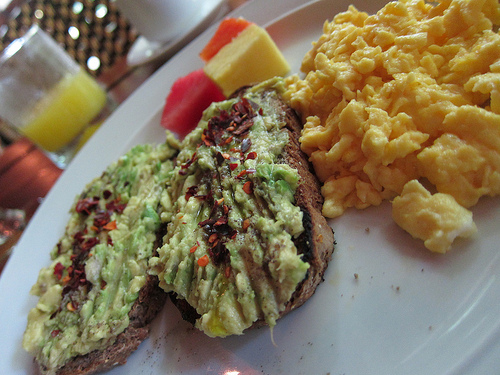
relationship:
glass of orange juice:
[3, 18, 109, 150] [20, 72, 107, 154]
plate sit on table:
[0, 0, 500, 375] [1, 10, 276, 265]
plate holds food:
[343, 286, 440, 362] [18, 90, 498, 287]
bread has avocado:
[170, 84, 337, 328] [146, 96, 311, 340]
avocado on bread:
[146, 96, 311, 340] [170, 84, 337, 328]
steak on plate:
[32, 84, 337, 373] [6, 3, 498, 373]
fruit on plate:
[162, 15, 290, 134] [6, 3, 498, 373]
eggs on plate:
[282, 0, 499, 250] [6, 3, 498, 373]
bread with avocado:
[247, 95, 342, 340] [146, 96, 311, 340]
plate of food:
[0, 0, 500, 375] [29, 3, 498, 366]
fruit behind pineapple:
[159, 17, 289, 135] [192, 19, 329, 106]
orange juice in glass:
[22, 66, 111, 157] [0, 19, 114, 159]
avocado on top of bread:
[23, 122, 320, 327] [170, 84, 337, 328]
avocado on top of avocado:
[146, 96, 311, 340] [23, 122, 320, 327]